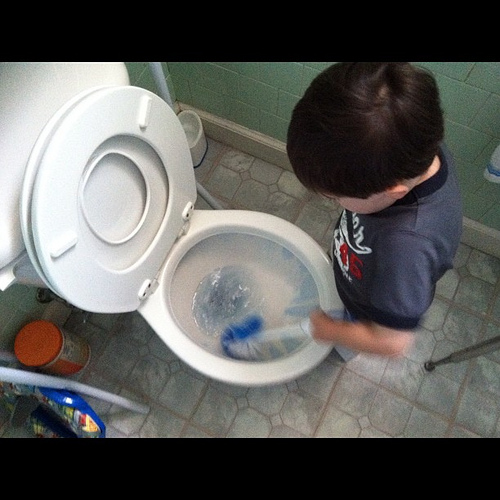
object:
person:
[281, 60, 460, 368]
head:
[286, 61, 444, 216]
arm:
[311, 305, 413, 356]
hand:
[310, 307, 331, 343]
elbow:
[363, 325, 410, 357]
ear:
[388, 185, 407, 199]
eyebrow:
[322, 194, 337, 202]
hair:
[288, 61, 444, 193]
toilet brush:
[222, 309, 345, 360]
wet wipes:
[14, 320, 89, 377]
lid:
[15, 320, 62, 367]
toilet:
[0, 61, 346, 388]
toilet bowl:
[172, 235, 319, 361]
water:
[194, 263, 265, 338]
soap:
[211, 270, 249, 311]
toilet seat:
[30, 85, 197, 313]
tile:
[438, 397, 500, 439]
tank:
[0, 63, 146, 291]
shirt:
[332, 142, 463, 329]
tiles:
[217, 151, 265, 209]